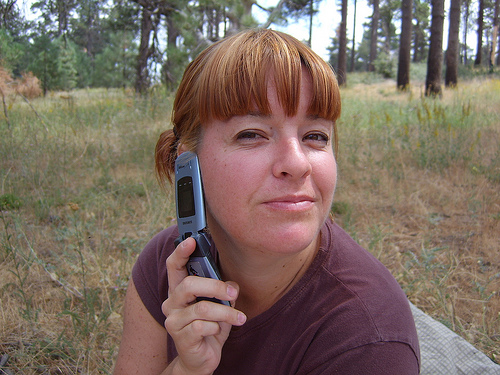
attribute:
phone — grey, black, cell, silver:
[172, 149, 235, 316]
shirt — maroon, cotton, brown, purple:
[129, 210, 423, 374]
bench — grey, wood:
[404, 296, 499, 375]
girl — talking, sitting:
[112, 28, 418, 374]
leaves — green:
[2, 23, 135, 89]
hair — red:
[154, 25, 343, 190]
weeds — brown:
[338, 167, 499, 327]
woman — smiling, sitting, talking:
[116, 27, 424, 374]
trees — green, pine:
[5, 0, 499, 96]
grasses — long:
[359, 82, 498, 145]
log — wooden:
[404, 295, 498, 374]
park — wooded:
[1, 0, 499, 147]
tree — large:
[132, 0, 168, 92]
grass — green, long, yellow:
[14, 98, 122, 127]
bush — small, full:
[1, 70, 45, 104]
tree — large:
[424, 0, 446, 104]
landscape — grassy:
[1, 77, 492, 360]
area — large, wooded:
[1, 1, 497, 374]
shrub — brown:
[1, 66, 46, 129]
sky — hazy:
[0, 1, 499, 47]